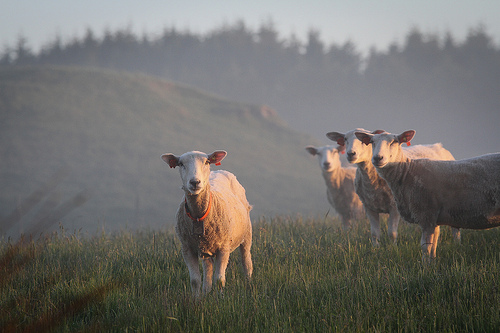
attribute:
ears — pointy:
[160, 125, 417, 166]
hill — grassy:
[1, 59, 368, 244]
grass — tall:
[0, 64, 500, 330]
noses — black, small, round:
[316, 142, 422, 186]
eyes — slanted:
[391, 137, 398, 146]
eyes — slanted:
[362, 137, 372, 144]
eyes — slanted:
[333, 145, 343, 156]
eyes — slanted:
[203, 155, 209, 165]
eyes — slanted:
[178, 157, 183, 167]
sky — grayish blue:
[293, 14, 401, 57]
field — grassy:
[295, 201, 432, 325]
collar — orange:
[182, 190, 213, 221]